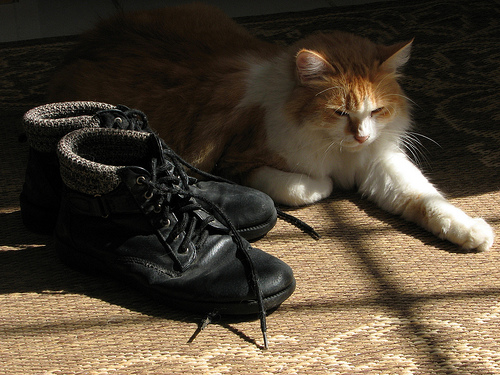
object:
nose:
[356, 137, 368, 142]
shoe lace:
[140, 179, 267, 349]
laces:
[136, 159, 214, 251]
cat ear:
[293, 47, 335, 82]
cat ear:
[379, 37, 414, 67]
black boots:
[58, 128, 295, 315]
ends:
[262, 332, 268, 349]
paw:
[447, 217, 495, 249]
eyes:
[334, 109, 349, 117]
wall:
[0, 0, 113, 43]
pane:
[0, 156, 499, 375]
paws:
[285, 172, 333, 206]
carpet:
[0, 150, 499, 375]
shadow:
[0, 0, 499, 210]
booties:
[22, 101, 275, 240]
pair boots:
[21, 99, 295, 315]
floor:
[0, 0, 492, 373]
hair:
[301, 56, 322, 75]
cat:
[52, 4, 495, 252]